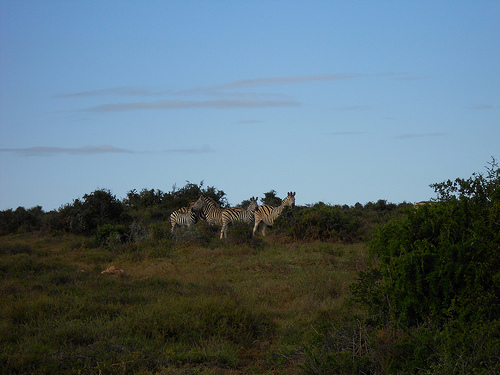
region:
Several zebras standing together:
[167, 189, 297, 241]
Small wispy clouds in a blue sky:
[0, 0, 497, 161]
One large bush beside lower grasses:
[335, 165, 497, 372]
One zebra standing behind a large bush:
[251, 191, 296, 251]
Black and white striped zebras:
[217, 196, 257, 237]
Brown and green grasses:
[97, 239, 370, 368]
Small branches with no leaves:
[315, 322, 377, 372]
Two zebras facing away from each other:
[188, 194, 259, 244]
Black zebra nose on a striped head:
[247, 194, 259, 214]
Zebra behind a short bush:
[217, 195, 258, 250]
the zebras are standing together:
[161, 184, 310, 244]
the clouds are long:
[0, 70, 498, 151]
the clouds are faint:
[1, 71, 498, 171]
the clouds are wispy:
[1, 70, 498, 161]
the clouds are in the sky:
[5, 70, 499, 163]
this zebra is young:
[163, 204, 202, 243]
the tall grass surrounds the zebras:
[4, 211, 498, 366]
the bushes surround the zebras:
[0, 176, 382, 263]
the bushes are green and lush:
[1, 148, 498, 330]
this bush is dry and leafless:
[124, 216, 204, 253]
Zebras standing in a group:
[95, 160, 372, 264]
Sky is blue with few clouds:
[147, 46, 352, 154]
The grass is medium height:
[76, 265, 248, 350]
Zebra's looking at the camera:
[139, 186, 339, 269]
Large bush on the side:
[347, 180, 478, 320]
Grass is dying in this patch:
[250, 256, 335, 313]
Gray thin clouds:
[132, 55, 320, 110]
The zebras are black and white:
[207, 211, 228, 220]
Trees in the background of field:
[15, 193, 175, 213]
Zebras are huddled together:
[151, 193, 318, 239]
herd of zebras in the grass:
[172, 187, 294, 239]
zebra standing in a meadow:
[252, 191, 299, 233]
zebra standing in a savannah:
[217, 198, 259, 240]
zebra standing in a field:
[165, 202, 199, 234]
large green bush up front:
[341, 175, 498, 373]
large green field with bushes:
[2, 206, 495, 371]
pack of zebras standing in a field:
[165, 190, 290, 236]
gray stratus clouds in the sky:
[1, 61, 491, 158]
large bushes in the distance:
[39, 185, 235, 230]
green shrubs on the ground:
[0, 248, 382, 366]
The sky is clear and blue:
[58, 11, 442, 69]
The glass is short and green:
[36, 285, 266, 355]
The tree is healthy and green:
[348, 150, 499, 373]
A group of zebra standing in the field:
[165, 186, 301, 245]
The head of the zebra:
[279, 189, 303, 211]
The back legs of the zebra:
[215, 216, 233, 243]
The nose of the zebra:
[285, 199, 300, 210]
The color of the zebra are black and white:
[219, 190, 299, 240]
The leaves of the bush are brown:
[283, 218, 342, 245]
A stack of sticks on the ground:
[279, 315, 392, 372]